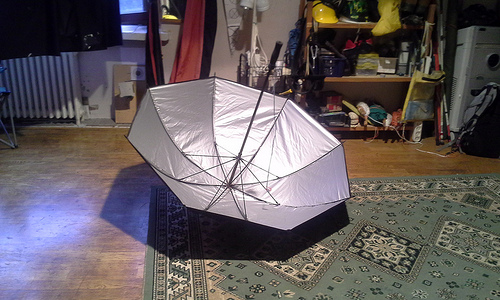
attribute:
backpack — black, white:
[448, 69, 496, 161]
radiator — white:
[4, 44, 84, 125]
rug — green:
[164, 185, 438, 297]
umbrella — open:
[125, 37, 354, 237]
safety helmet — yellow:
[307, 1, 337, 19]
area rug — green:
[141, 177, 481, 295]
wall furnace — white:
[5, 50, 91, 116]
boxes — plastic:
[355, 50, 377, 78]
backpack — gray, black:
[453, 85, 484, 164]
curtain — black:
[6, 4, 131, 55]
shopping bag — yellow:
[371, 5, 411, 39]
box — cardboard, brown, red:
[326, 95, 337, 111]